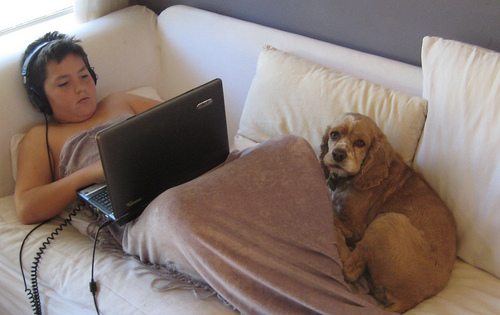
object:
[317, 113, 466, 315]
dog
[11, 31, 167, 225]
boy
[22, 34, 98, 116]
headphone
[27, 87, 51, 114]
ears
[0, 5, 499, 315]
couch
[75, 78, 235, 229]
laptop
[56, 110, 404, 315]
blanket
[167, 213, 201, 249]
cords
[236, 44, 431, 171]
pillow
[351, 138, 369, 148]
dogs ears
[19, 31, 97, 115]
hair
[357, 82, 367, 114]
wrinkles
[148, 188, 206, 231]
lap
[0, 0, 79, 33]
window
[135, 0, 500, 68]
wall